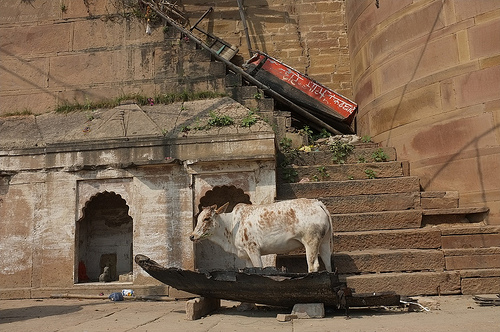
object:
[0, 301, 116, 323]
shadow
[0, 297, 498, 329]
ground